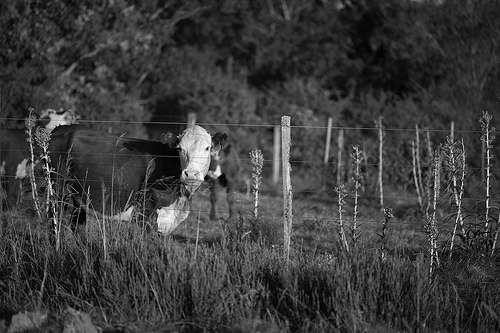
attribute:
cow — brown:
[43, 95, 250, 267]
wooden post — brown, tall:
[267, 106, 317, 280]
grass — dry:
[227, 237, 305, 329]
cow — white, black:
[24, 99, 218, 232]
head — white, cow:
[168, 120, 218, 188]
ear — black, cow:
[211, 130, 227, 147]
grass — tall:
[208, 246, 308, 297]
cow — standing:
[51, 120, 213, 243]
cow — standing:
[35, 112, 235, 232]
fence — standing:
[122, 125, 205, 223]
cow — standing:
[50, 112, 227, 232]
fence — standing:
[138, 120, 208, 260]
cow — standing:
[35, 120, 221, 235]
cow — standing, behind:
[45, 154, 251, 233]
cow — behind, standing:
[31, 128, 229, 283]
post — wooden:
[273, 113, 308, 267]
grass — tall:
[30, 177, 490, 329]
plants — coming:
[94, 190, 140, 259]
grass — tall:
[42, 173, 490, 319]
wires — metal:
[33, 108, 282, 268]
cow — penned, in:
[26, 126, 236, 277]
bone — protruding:
[66, 118, 77, 151]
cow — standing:
[37, 111, 230, 279]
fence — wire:
[14, 98, 498, 298]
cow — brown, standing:
[33, 109, 227, 251]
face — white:
[177, 122, 217, 176]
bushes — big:
[10, 199, 251, 329]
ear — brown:
[205, 127, 230, 154]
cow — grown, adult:
[38, 119, 234, 249]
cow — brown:
[35, 112, 218, 258]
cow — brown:
[57, 113, 224, 243]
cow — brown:
[50, 104, 229, 281]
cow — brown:
[25, 100, 235, 274]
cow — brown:
[51, 110, 243, 252]